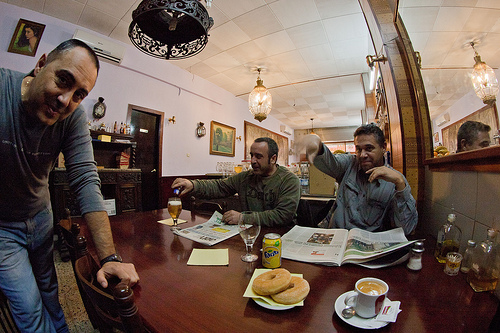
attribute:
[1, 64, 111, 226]
shirt — grey 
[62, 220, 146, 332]
chair — empty 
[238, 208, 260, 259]
glass — empty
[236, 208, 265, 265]
glass — empty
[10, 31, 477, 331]
men — three, in a room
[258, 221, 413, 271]
newspaper — open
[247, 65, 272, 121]
light — glass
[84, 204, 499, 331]
table — brown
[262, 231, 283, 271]
can — yellow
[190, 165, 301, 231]
shirt — green